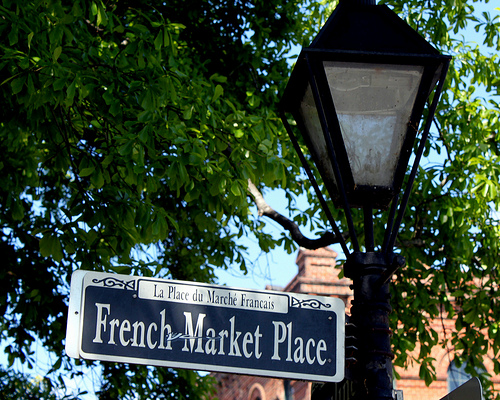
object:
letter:
[130, 320, 147, 348]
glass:
[321, 61, 424, 188]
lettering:
[91, 283, 328, 366]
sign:
[61, 268, 346, 383]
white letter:
[315, 338, 327, 364]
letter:
[268, 320, 288, 361]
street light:
[273, 0, 451, 399]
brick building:
[184, 246, 498, 399]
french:
[91, 301, 174, 350]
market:
[179, 311, 264, 359]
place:
[270, 321, 328, 365]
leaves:
[214, 95, 239, 119]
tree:
[0, 0, 499, 399]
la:
[152, 283, 163, 298]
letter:
[154, 308, 173, 351]